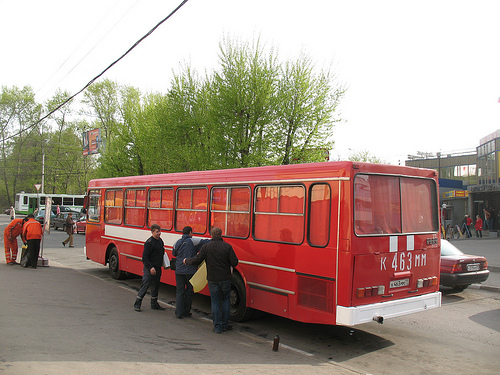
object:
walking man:
[61, 212, 76, 248]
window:
[122, 187, 146, 227]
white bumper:
[335, 290, 442, 325]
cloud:
[156, 0, 493, 159]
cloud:
[0, 0, 105, 137]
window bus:
[305, 180, 333, 250]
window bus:
[145, 188, 174, 230]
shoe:
[150, 302, 167, 310]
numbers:
[391, 253, 398, 271]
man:
[4, 216, 31, 266]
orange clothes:
[3, 218, 27, 243]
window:
[87, 186, 100, 226]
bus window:
[103, 188, 124, 225]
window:
[208, 191, 250, 231]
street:
[1, 210, 498, 373]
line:
[0, 0, 185, 142]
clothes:
[141, 236, 165, 271]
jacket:
[22, 218, 42, 243]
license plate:
[389, 278, 410, 288]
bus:
[84, 160, 441, 327]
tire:
[108, 247, 124, 280]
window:
[250, 182, 306, 246]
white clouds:
[173, 35, 207, 60]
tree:
[133, 31, 344, 166]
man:
[183, 227, 240, 335]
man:
[172, 225, 210, 319]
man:
[133, 224, 169, 313]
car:
[438, 238, 491, 290]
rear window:
[349, 170, 440, 236]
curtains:
[354, 174, 440, 236]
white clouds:
[362, 67, 444, 137]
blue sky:
[0, 0, 498, 164]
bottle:
[272, 333, 280, 352]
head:
[150, 223, 161, 237]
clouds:
[34, 33, 480, 92]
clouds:
[35, 6, 97, 60]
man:
[22, 213, 42, 269]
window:
[102, 186, 126, 226]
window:
[174, 183, 206, 235]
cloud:
[380, 29, 410, 68]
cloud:
[232, 7, 289, 48]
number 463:
[391, 251, 412, 271]